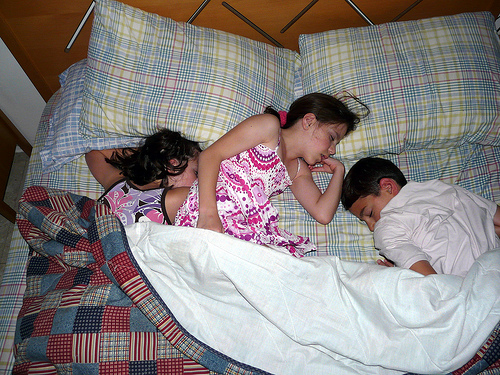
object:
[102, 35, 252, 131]
pillow part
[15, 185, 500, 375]
blanket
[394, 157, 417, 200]
ground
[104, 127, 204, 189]
hair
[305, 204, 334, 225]
elbow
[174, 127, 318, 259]
dress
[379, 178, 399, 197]
ear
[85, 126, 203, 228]
girl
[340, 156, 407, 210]
hair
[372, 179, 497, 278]
shirt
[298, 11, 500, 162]
pillow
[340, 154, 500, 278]
boy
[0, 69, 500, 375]
sheets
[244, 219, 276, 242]
pattern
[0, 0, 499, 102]
head board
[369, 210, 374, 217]
eyes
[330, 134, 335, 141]
eyes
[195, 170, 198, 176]
eyes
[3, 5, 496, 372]
photo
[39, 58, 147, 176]
small pillow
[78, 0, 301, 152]
big pillow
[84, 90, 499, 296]
family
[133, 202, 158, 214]
purple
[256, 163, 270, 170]
pink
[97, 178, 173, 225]
shirt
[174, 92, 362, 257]
girl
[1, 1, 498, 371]
bed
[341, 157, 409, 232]
head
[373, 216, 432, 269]
sleeve